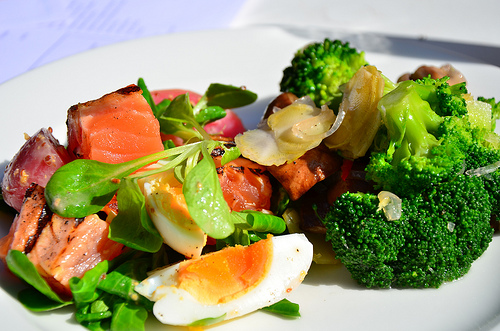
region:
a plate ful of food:
[45, 65, 480, 292]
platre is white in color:
[116, 54, 267, 83]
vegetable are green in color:
[371, 191, 484, 264]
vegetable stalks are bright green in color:
[386, 89, 448, 146]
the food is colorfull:
[61, 102, 350, 313]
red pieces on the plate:
[57, 100, 153, 142]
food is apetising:
[71, 69, 367, 286]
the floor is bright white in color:
[20, 4, 142, 46]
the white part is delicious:
[150, 248, 305, 306]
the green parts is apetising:
[115, 170, 260, 231]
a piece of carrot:
[15, 190, 47, 244]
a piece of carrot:
[69, 227, 111, 254]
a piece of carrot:
[40, 225, 64, 242]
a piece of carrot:
[80, 102, 147, 149]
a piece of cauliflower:
[334, 184, 482, 279]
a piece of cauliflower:
[406, 79, 471, 159]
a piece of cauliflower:
[304, 36, 338, 98]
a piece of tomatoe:
[232, 172, 266, 197]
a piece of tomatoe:
[26, 137, 52, 169]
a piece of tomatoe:
[221, 114, 233, 128]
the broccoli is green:
[350, 181, 477, 287]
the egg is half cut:
[158, 230, 330, 325]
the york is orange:
[186, 237, 278, 295]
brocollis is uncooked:
[393, 85, 495, 172]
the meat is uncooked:
[78, 86, 164, 146]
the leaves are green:
[57, 152, 128, 197]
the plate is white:
[107, 50, 246, 73]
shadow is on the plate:
[320, 274, 344, 286]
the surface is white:
[78, 15, 140, 32]